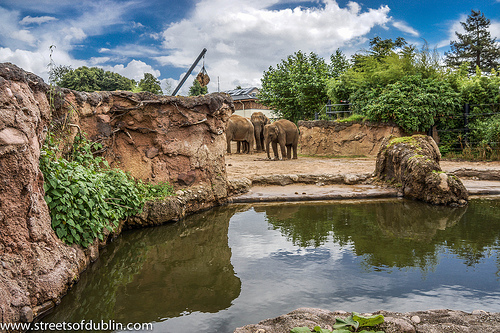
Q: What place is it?
A: It is a swimming pool.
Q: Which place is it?
A: It is a swimming pool.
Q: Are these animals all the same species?
A: Yes, all the animals are elephants.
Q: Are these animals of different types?
A: No, all the animals are elephants.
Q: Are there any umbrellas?
A: No, there are no umbrellas.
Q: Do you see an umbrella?
A: No, there are no umbrellas.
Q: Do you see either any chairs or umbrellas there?
A: No, there are no umbrellas or chairs.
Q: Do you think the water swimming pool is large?
A: Yes, the swimming pool is large.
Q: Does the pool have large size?
A: Yes, the pool is large.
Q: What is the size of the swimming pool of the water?
A: The swimming pool is large.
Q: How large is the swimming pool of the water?
A: The swimming pool is large.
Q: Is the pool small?
A: No, the pool is large.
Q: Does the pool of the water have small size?
A: No, the pool is large.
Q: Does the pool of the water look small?
A: No, the pool is large.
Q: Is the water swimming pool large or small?
A: The swimming pool is large.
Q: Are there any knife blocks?
A: No, there are no knife blocks.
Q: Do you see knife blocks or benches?
A: No, there are no knife blocks or benches.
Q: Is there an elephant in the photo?
A: Yes, there is an elephant.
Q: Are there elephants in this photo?
A: Yes, there is an elephant.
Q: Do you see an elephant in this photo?
A: Yes, there is an elephant.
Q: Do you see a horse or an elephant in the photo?
A: Yes, there is an elephant.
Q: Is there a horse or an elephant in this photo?
A: Yes, there is an elephant.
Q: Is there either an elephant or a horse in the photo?
A: Yes, there is an elephant.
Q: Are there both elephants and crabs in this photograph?
A: No, there is an elephant but no crabs.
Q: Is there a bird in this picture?
A: No, there are no birds.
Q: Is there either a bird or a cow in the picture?
A: No, there are no birds or cows.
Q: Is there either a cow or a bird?
A: No, there are no birds or cows.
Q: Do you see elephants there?
A: Yes, there is an elephant.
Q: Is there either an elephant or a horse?
A: Yes, there is an elephant.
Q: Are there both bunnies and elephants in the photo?
A: No, there is an elephant but no bunnies.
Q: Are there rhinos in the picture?
A: No, there are no rhinos.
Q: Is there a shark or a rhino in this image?
A: No, there are no rhinos or sharks.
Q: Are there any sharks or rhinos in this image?
A: No, there are no rhinos or sharks.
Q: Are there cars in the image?
A: No, there are no cars.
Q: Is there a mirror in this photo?
A: No, there are no mirrors.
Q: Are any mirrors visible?
A: No, there are no mirrors.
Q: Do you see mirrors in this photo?
A: No, there are no mirrors.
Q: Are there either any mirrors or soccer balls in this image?
A: No, there are no mirrors or soccer balls.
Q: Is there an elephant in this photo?
A: Yes, there is an elephant.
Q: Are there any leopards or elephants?
A: Yes, there is an elephant.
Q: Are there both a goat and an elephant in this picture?
A: No, there is an elephant but no goats.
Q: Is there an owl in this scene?
A: No, there are no owls.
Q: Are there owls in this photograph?
A: No, there are no owls.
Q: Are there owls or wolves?
A: No, there are no owls or wolves.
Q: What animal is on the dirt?
A: The elephant is on the dirt.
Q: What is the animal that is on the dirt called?
A: The animal is an elephant.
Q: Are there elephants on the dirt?
A: Yes, there is an elephant on the dirt.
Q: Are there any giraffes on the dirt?
A: No, there is an elephant on the dirt.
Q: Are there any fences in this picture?
A: Yes, there is a fence.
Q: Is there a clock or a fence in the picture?
A: Yes, there is a fence.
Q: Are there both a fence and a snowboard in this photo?
A: No, there is a fence but no snowboards.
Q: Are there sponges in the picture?
A: No, there are no sponges.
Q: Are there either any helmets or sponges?
A: No, there are no sponges or helmets.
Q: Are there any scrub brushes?
A: No, there are no scrub brushes.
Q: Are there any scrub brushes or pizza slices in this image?
A: No, there are no scrub brushes or pizza slices.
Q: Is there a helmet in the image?
A: No, there are no helmets.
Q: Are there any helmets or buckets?
A: No, there are no helmets or buckets.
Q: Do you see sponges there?
A: No, there are no sponges.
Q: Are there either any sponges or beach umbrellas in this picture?
A: No, there are no sponges or beach umbrellas.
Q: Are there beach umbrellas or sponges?
A: No, there are no sponges or beach umbrellas.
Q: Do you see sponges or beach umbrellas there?
A: No, there are no sponges or beach umbrellas.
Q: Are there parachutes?
A: No, there are no parachutes.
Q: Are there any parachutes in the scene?
A: No, there are no parachutes.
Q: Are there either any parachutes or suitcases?
A: No, there are no parachutes or suitcases.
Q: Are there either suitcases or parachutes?
A: No, there are no parachutes or suitcases.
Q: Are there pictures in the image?
A: No, there are no pictures.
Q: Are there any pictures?
A: No, there are no pictures.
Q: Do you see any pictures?
A: No, there are no pictures.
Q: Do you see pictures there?
A: No, there are no pictures.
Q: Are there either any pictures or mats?
A: No, there are no pictures or mats.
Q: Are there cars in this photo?
A: No, there are no cars.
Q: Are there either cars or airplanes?
A: No, there are no cars or airplanes.